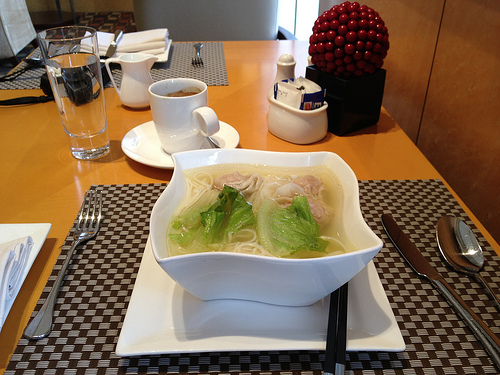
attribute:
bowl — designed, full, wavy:
[151, 249, 381, 308]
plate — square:
[114, 288, 407, 357]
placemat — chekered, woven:
[7, 183, 162, 375]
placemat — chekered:
[172, 42, 228, 85]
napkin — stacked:
[121, 28, 171, 60]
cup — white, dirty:
[150, 77, 220, 153]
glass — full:
[35, 26, 111, 162]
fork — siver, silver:
[24, 191, 104, 340]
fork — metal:
[192, 41, 204, 67]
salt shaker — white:
[274, 55, 296, 87]